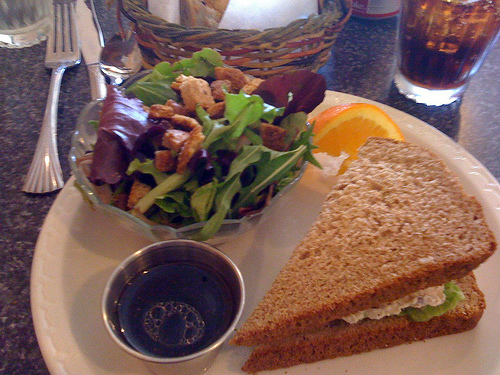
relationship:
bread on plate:
[230, 137, 498, 374] [29, 86, 497, 373]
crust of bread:
[227, 243, 496, 373] [230, 137, 498, 374]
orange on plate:
[302, 101, 404, 177] [29, 86, 497, 373]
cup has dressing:
[82, 231, 250, 365] [127, 264, 219, 334]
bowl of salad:
[73, 128, 173, 235] [78, 31, 301, 246]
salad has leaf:
[74, 46, 328, 243] [253, 65, 327, 115]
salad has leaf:
[74, 46, 328, 243] [212, 88, 264, 142]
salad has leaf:
[74, 46, 328, 243] [102, 81, 163, 153]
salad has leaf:
[74, 46, 328, 243] [87, 130, 126, 189]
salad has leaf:
[74, 46, 328, 243] [233, 142, 313, 212]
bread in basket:
[179, 0, 228, 26] [114, 0, 351, 80]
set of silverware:
[19, 9, 119, 205] [30, 6, 113, 197]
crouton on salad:
[179, 79, 213, 109] [74, 46, 328, 243]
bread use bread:
[230, 137, 498, 374] [305, 157, 482, 332]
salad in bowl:
[74, 46, 328, 243] [73, 128, 298, 234]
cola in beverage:
[401, 2, 470, 80] [393, 4, 493, 84]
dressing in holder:
[127, 264, 219, 334] [115, 232, 225, 266]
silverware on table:
[18, 0, 83, 197] [0, 0, 497, 374]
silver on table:
[104, 38, 134, 71] [0, 0, 497, 374]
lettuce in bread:
[407, 280, 464, 331] [230, 137, 498, 374]